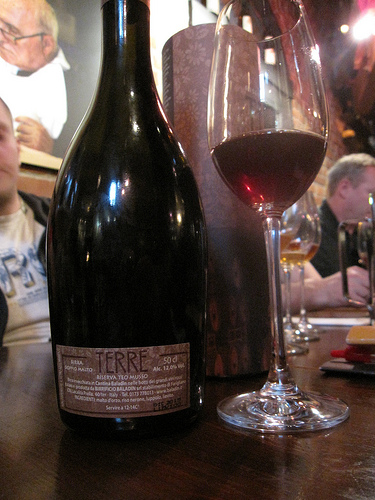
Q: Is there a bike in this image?
A: No, there are no bikes.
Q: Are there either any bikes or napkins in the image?
A: No, there are no bikes or napkins.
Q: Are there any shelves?
A: No, there are no shelves.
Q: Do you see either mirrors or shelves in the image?
A: No, there are no shelves or mirrors.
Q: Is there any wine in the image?
A: Yes, there is wine.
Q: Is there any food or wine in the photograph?
A: Yes, there is wine.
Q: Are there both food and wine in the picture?
A: No, there is wine but no food.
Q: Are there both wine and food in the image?
A: No, there is wine but no food.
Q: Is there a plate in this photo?
A: No, there are no plates.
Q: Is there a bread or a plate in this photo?
A: No, there are no plates or breads.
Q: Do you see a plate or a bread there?
A: No, there are no plates or breads.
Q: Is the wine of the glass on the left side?
A: No, the wine is on the right of the image.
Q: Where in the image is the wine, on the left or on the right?
A: The wine is on the right of the image.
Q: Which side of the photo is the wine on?
A: The wine is on the right of the image.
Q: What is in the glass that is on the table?
A: The wine is in the glass.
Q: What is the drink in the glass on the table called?
A: The drink is wine.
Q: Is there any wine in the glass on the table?
A: Yes, there is wine in the glass.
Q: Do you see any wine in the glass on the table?
A: Yes, there is wine in the glass.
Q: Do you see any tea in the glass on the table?
A: No, there is wine in the glass.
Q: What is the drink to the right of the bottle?
A: The drink is wine.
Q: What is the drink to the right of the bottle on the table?
A: The drink is wine.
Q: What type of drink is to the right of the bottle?
A: The drink is wine.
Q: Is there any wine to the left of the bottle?
A: No, the wine is to the right of the bottle.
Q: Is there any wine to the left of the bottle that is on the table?
A: No, the wine is to the right of the bottle.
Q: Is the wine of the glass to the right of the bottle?
A: Yes, the wine is to the right of the bottle.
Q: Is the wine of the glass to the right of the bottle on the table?
A: Yes, the wine is to the right of the bottle.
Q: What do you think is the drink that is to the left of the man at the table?
A: The drink is wine.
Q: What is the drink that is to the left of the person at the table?
A: The drink is wine.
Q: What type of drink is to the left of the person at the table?
A: The drink is wine.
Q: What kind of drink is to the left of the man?
A: The drink is wine.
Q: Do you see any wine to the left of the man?
A: Yes, there is wine to the left of the man.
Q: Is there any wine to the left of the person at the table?
A: Yes, there is wine to the left of the man.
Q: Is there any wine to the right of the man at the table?
A: No, the wine is to the left of the man.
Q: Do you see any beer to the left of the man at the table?
A: No, there is wine to the left of the man.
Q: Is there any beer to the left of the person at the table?
A: No, there is wine to the left of the man.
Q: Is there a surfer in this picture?
A: No, there are no surfers.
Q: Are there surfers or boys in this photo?
A: No, there are no surfers or boys.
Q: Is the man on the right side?
A: Yes, the man is on the right of the image.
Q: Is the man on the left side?
A: No, the man is on the right of the image.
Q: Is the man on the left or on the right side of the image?
A: The man is on the right of the image.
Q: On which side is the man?
A: The man is on the right of the image.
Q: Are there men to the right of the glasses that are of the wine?
A: Yes, there is a man to the right of the glasses.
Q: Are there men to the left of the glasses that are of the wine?
A: No, the man is to the right of the glasses.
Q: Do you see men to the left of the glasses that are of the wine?
A: No, the man is to the right of the glasses.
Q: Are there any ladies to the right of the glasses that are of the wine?
A: No, there is a man to the right of the glasses.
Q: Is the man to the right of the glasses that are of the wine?
A: Yes, the man is to the right of the glasses.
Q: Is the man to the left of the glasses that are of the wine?
A: No, the man is to the right of the glasses.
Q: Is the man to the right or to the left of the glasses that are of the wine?
A: The man is to the right of the glasses.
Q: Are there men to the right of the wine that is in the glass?
A: Yes, there is a man to the right of the wine.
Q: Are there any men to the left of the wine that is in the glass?
A: No, the man is to the right of the wine.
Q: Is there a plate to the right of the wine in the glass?
A: No, there is a man to the right of the wine.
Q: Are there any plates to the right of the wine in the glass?
A: No, there is a man to the right of the wine.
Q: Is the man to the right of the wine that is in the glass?
A: Yes, the man is to the right of the wine.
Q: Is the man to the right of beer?
A: No, the man is to the right of the wine.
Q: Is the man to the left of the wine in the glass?
A: No, the man is to the right of the wine.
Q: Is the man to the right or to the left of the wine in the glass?
A: The man is to the right of the wine.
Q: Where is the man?
A: The man is at the table.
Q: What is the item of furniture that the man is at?
A: The piece of furniture is a table.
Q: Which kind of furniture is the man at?
A: The man is at the table.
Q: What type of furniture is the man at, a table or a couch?
A: The man is at a table.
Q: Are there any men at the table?
A: Yes, there is a man at the table.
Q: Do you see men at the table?
A: Yes, there is a man at the table.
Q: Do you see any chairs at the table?
A: No, there is a man at the table.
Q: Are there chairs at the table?
A: No, there is a man at the table.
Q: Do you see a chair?
A: No, there are no chairs.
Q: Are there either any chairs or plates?
A: No, there are no chairs or plates.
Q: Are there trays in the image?
A: No, there are no trays.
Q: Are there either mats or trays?
A: No, there are no trays or mats.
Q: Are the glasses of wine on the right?
A: Yes, the glasses are on the right of the image.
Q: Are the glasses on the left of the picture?
A: No, the glasses are on the right of the image.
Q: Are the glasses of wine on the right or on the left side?
A: The glasses are on the right of the image.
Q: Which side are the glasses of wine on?
A: The glasses are on the right of the image.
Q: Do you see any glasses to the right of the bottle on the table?
A: Yes, there are glasses to the right of the bottle.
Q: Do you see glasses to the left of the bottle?
A: No, the glasses are to the right of the bottle.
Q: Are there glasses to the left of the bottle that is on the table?
A: No, the glasses are to the right of the bottle.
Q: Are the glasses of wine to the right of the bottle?
A: Yes, the glasses are to the right of the bottle.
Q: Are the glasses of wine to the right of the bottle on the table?
A: Yes, the glasses are to the right of the bottle.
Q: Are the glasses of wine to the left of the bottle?
A: No, the glasses are to the right of the bottle.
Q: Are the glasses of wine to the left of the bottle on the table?
A: No, the glasses are to the right of the bottle.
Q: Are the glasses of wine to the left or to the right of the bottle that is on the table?
A: The glasses are to the right of the bottle.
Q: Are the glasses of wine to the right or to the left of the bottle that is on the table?
A: The glasses are to the right of the bottle.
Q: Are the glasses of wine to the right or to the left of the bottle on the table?
A: The glasses are to the right of the bottle.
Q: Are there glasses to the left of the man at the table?
A: Yes, there are glasses to the left of the man.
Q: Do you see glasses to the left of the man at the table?
A: Yes, there are glasses to the left of the man.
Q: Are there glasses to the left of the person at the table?
A: Yes, there are glasses to the left of the man.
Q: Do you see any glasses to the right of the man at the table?
A: No, the glasses are to the left of the man.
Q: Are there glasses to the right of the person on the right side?
A: No, the glasses are to the left of the man.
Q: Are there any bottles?
A: Yes, there is a bottle.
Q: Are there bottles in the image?
A: Yes, there is a bottle.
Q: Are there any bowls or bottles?
A: Yes, there is a bottle.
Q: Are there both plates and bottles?
A: No, there is a bottle but no plates.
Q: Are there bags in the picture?
A: No, there are no bags.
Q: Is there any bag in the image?
A: No, there are no bags.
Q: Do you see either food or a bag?
A: No, there are no bags or food.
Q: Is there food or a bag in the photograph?
A: No, there are no bags or food.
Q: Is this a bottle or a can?
A: This is a bottle.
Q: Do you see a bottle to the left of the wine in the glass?
A: Yes, there is a bottle to the left of the wine.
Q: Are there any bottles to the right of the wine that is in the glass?
A: No, the bottle is to the left of the wine.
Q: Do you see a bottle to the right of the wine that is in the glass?
A: No, the bottle is to the left of the wine.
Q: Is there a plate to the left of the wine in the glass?
A: No, there is a bottle to the left of the wine.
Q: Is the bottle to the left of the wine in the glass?
A: Yes, the bottle is to the left of the wine.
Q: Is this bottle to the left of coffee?
A: No, the bottle is to the left of the wine.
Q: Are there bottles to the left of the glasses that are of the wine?
A: Yes, there is a bottle to the left of the glasses.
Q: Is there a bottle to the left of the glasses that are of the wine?
A: Yes, there is a bottle to the left of the glasses.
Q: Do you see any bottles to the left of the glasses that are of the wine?
A: Yes, there is a bottle to the left of the glasses.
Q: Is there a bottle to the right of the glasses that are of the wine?
A: No, the bottle is to the left of the glasses.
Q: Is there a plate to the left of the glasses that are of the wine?
A: No, there is a bottle to the left of the glasses.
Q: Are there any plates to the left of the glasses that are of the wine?
A: No, there is a bottle to the left of the glasses.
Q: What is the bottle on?
A: The bottle is on the table.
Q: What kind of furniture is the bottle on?
A: The bottle is on the table.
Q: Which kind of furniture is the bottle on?
A: The bottle is on the table.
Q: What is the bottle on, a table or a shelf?
A: The bottle is on a table.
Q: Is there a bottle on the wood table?
A: Yes, there is a bottle on the table.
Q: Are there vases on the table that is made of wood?
A: No, there is a bottle on the table.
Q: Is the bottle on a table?
A: Yes, the bottle is on a table.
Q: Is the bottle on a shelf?
A: No, the bottle is on a table.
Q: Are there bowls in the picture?
A: No, there are no bowls.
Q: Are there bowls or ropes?
A: No, there are no bowls or ropes.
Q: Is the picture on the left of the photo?
A: Yes, the picture is on the left of the image.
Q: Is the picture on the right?
A: No, the picture is on the left of the image.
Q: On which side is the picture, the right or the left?
A: The picture is on the left of the image.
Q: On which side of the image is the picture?
A: The picture is on the left of the image.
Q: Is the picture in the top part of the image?
A: Yes, the picture is in the top of the image.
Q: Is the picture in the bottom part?
A: No, the picture is in the top of the image.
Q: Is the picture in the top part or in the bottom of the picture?
A: The picture is in the top of the image.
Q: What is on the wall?
A: The picture is on the wall.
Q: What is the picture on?
A: The picture is on the wall.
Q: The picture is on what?
A: The picture is on the wall.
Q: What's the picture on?
A: The picture is on the wall.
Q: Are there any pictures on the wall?
A: Yes, there is a picture on the wall.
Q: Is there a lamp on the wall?
A: No, there is a picture on the wall.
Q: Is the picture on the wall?
A: Yes, the picture is on the wall.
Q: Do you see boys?
A: No, there are no boys.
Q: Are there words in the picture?
A: Yes, there are words.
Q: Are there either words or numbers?
A: Yes, there are words.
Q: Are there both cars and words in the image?
A: No, there are words but no cars.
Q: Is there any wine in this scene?
A: Yes, there is wine.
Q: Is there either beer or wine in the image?
A: Yes, there is wine.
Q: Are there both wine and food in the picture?
A: No, there is wine but no food.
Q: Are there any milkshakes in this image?
A: No, there are no milkshakes.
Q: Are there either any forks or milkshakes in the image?
A: No, there are no milkshakes or forks.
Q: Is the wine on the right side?
A: Yes, the wine is on the right of the image.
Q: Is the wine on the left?
A: No, the wine is on the right of the image.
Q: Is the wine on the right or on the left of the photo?
A: The wine is on the right of the image.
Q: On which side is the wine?
A: The wine is on the right of the image.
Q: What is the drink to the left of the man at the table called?
A: The drink is wine.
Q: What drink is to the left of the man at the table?
A: The drink is wine.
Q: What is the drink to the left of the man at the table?
A: The drink is wine.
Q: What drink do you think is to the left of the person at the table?
A: The drink is wine.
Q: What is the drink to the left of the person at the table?
A: The drink is wine.